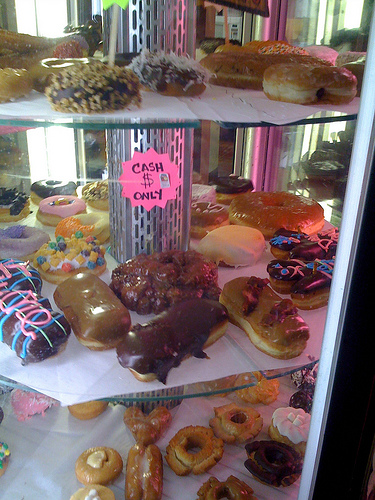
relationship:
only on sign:
[126, 188, 172, 213] [110, 132, 192, 227]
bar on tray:
[226, 275, 310, 355] [1, 179, 340, 385]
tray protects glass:
[0, 46, 359, 131] [2, 0, 358, 495]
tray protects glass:
[0, 184, 328, 400] [2, 0, 358, 495]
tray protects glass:
[0, 370, 318, 500] [2, 0, 358, 495]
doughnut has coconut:
[134, 58, 209, 97] [126, 43, 210, 71]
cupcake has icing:
[270, 232, 296, 262] [269, 231, 300, 243]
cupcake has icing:
[270, 232, 296, 262] [287, 263, 302, 281]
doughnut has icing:
[34, 195, 88, 228] [55, 205, 76, 214]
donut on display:
[78, 444, 119, 484] [4, 0, 374, 498]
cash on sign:
[130, 160, 172, 175] [117, 146, 184, 212]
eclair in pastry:
[115, 297, 228, 385] [27, 276, 263, 351]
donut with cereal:
[36, 238, 96, 269] [33, 227, 108, 270]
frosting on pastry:
[266, 266, 281, 280] [264, 254, 308, 286]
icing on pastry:
[286, 265, 304, 279] [264, 254, 308, 286]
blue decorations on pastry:
[272, 262, 286, 273] [264, 254, 308, 286]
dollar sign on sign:
[140, 173, 155, 191] [117, 146, 184, 212]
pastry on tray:
[71, 445, 120, 482] [7, 406, 308, 497]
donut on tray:
[166, 421, 224, 478] [0, 362, 318, 498]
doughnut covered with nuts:
[44, 61, 143, 114] [44, 58, 142, 111]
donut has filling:
[75, 445, 123, 486] [84, 448, 107, 468]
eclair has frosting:
[114, 297, 227, 381] [112, 296, 226, 386]